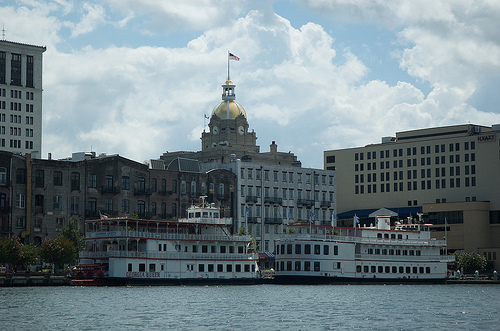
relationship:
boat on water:
[93, 220, 281, 282] [0, 277, 497, 330]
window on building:
[351, 150, 371, 163] [327, 139, 495, 264]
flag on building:
[213, 43, 250, 79] [190, 75, 272, 161]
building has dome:
[190, 75, 272, 161] [208, 80, 249, 118]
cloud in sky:
[65, 39, 208, 131] [26, 9, 498, 138]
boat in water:
[93, 220, 281, 282] [0, 277, 497, 330]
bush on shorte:
[457, 253, 476, 269] [454, 263, 499, 285]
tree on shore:
[16, 243, 72, 269] [8, 268, 57, 286]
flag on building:
[213, 43, 250, 79] [327, 139, 495, 264]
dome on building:
[208, 80, 249, 118] [190, 75, 272, 161]